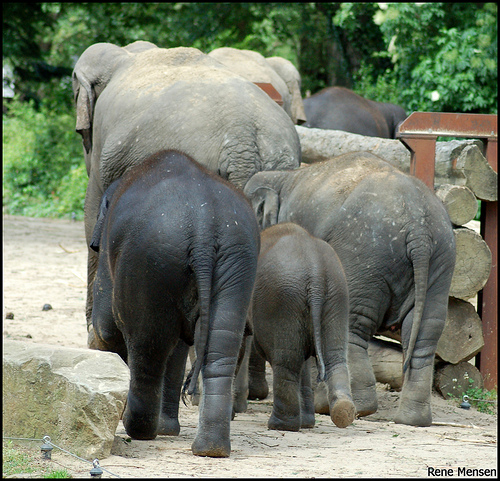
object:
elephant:
[88, 148, 261, 457]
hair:
[128, 147, 217, 188]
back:
[129, 172, 250, 220]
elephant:
[231, 222, 356, 431]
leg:
[321, 318, 356, 428]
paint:
[336, 169, 384, 188]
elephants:
[242, 150, 457, 427]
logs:
[433, 361, 484, 400]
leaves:
[106, 8, 208, 43]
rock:
[0, 342, 133, 462]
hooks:
[40, 436, 54, 462]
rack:
[394, 111, 498, 406]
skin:
[186, 108, 261, 134]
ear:
[70, 70, 95, 155]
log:
[435, 139, 500, 225]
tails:
[187, 230, 218, 395]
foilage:
[379, 23, 467, 88]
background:
[0, 0, 500, 63]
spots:
[167, 170, 171, 172]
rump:
[114, 210, 259, 305]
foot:
[329, 387, 356, 428]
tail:
[402, 225, 433, 373]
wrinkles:
[99, 130, 145, 189]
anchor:
[88, 458, 104, 479]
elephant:
[71, 40, 301, 351]